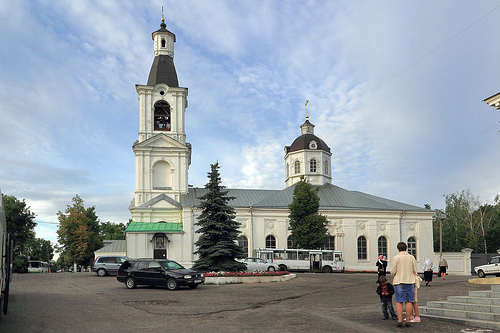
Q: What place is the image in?
A: It is at the church.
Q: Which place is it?
A: It is a church.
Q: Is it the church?
A: Yes, it is the church.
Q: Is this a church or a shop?
A: It is a church.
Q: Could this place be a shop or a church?
A: It is a church.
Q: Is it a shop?
A: No, it is a church.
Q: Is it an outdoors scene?
A: Yes, it is outdoors.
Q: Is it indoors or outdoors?
A: It is outdoors.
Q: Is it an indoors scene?
A: No, it is outdoors.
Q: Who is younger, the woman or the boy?
A: The boy is younger than the woman.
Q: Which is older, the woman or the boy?
A: The woman is older than the boy.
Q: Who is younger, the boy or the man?
A: The boy is younger than the man.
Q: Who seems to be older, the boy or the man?
A: The man is older than the boy.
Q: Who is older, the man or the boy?
A: The man is older than the boy.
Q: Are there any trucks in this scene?
A: No, there are no trucks.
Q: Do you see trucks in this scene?
A: No, there are no trucks.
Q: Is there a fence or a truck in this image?
A: No, there are no trucks or fences.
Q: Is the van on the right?
A: No, the van is on the left of the image.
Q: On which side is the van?
A: The van is on the left of the image.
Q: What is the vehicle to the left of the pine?
A: The vehicle is a van.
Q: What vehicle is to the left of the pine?
A: The vehicle is a van.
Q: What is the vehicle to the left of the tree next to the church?
A: The vehicle is a van.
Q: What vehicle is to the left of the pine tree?
A: The vehicle is a van.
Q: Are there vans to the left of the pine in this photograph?
A: Yes, there is a van to the left of the pine.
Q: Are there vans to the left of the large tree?
A: Yes, there is a van to the left of the pine.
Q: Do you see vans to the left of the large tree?
A: Yes, there is a van to the left of the pine.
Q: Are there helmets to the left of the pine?
A: No, there is a van to the left of the pine.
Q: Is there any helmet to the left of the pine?
A: No, there is a van to the left of the pine.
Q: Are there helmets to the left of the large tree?
A: No, there is a van to the left of the pine.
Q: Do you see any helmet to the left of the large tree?
A: No, there is a van to the left of the pine.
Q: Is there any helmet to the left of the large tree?
A: No, there is a van to the left of the pine.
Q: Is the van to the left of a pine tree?
A: Yes, the van is to the left of a pine tree.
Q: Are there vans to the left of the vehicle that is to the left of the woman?
A: Yes, there is a van to the left of the bus.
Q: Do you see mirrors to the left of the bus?
A: No, there is a van to the left of the bus.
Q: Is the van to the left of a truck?
A: No, the van is to the left of a bus.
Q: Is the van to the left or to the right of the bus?
A: The van is to the left of the bus.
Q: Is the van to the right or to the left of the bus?
A: The van is to the left of the bus.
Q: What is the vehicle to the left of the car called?
A: The vehicle is a van.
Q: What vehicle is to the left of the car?
A: The vehicle is a van.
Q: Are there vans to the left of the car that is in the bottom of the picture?
A: Yes, there is a van to the left of the car.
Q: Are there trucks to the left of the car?
A: No, there is a van to the left of the car.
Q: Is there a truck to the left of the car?
A: No, there is a van to the left of the car.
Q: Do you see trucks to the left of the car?
A: No, there is a van to the left of the car.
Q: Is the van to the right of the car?
A: No, the van is to the left of the car.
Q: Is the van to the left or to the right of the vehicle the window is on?
A: The van is to the left of the car.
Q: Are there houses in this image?
A: No, there are no houses.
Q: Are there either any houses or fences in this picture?
A: No, there are no houses or fences.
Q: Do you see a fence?
A: No, there are no fences.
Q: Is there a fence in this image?
A: No, there are no fences.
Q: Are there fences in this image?
A: No, there are no fences.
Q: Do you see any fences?
A: No, there are no fences.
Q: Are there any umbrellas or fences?
A: No, there are no fences or umbrellas.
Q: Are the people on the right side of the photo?
A: Yes, the people are on the right of the image.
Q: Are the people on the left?
A: No, the people are on the right of the image.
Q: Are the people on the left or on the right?
A: The people are on the right of the image.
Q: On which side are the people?
A: The people are on the right of the image.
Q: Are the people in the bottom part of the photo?
A: Yes, the people are in the bottom of the image.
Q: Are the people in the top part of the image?
A: No, the people are in the bottom of the image.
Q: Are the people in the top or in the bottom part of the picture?
A: The people are in the bottom of the image.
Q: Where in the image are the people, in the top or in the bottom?
A: The people are in the bottom of the image.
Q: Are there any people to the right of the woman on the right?
A: Yes, there are people to the right of the woman.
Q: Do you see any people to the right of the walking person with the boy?
A: Yes, there are people to the right of the woman.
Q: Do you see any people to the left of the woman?
A: No, the people are to the right of the woman.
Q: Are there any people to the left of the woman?
A: No, the people are to the right of the woman.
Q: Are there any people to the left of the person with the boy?
A: No, the people are to the right of the woman.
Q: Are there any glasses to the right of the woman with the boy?
A: No, there are people to the right of the woman.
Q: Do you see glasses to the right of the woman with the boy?
A: No, there are people to the right of the woman.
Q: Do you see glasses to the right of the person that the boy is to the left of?
A: No, there are people to the right of the woman.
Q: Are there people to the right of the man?
A: Yes, there are people to the right of the man.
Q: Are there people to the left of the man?
A: No, the people are to the right of the man.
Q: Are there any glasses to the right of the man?
A: No, there are people to the right of the man.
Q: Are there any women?
A: Yes, there is a woman.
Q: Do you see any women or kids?
A: Yes, there is a woman.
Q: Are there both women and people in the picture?
A: Yes, there are both a woman and a person.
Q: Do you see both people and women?
A: Yes, there are both a woman and a person.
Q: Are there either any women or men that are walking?
A: Yes, the woman is walking.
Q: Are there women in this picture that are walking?
A: Yes, there is a woman that is walking.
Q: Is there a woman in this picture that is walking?
A: Yes, there is a woman that is walking.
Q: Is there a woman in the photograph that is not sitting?
A: Yes, there is a woman that is walking.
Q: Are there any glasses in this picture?
A: No, there are no glasses.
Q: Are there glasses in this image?
A: No, there are no glasses.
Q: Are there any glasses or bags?
A: No, there are no glasses or bags.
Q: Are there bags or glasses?
A: No, there are no glasses or bags.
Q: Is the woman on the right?
A: Yes, the woman is on the right of the image.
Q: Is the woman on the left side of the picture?
A: No, the woman is on the right of the image.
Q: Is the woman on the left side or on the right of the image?
A: The woman is on the right of the image.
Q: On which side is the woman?
A: The woman is on the right of the image.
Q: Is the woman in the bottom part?
A: Yes, the woman is in the bottom of the image.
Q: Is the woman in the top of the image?
A: No, the woman is in the bottom of the image.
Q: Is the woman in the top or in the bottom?
A: The woman is in the bottom of the image.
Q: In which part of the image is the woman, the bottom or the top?
A: The woman is in the bottom of the image.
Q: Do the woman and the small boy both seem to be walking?
A: Yes, both the woman and the boy are walking.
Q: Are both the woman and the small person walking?
A: Yes, both the woman and the boy are walking.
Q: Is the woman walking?
A: Yes, the woman is walking.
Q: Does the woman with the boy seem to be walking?
A: Yes, the woman is walking.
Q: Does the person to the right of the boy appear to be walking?
A: Yes, the woman is walking.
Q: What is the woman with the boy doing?
A: The woman is walking.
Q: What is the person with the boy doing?
A: The woman is walking.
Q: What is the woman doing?
A: The woman is walking.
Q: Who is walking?
A: The woman is walking.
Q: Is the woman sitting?
A: No, the woman is walking.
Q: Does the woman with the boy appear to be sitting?
A: No, the woman is walking.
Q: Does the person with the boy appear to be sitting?
A: No, the woman is walking.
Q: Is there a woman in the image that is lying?
A: No, there is a woman but she is walking.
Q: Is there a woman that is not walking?
A: No, there is a woman but she is walking.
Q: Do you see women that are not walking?
A: No, there is a woman but she is walking.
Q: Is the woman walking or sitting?
A: The woman is walking.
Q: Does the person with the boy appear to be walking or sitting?
A: The woman is walking.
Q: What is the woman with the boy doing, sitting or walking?
A: The woman is walking.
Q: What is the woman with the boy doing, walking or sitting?
A: The woman is walking.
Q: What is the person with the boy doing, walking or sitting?
A: The woman is walking.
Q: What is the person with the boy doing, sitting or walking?
A: The woman is walking.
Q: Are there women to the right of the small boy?
A: Yes, there is a woman to the right of the boy.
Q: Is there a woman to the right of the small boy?
A: Yes, there is a woman to the right of the boy.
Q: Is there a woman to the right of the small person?
A: Yes, there is a woman to the right of the boy.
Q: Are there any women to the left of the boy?
A: No, the woman is to the right of the boy.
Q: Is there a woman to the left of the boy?
A: No, the woman is to the right of the boy.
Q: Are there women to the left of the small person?
A: No, the woman is to the right of the boy.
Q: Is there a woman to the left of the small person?
A: No, the woman is to the right of the boy.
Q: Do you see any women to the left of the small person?
A: No, the woman is to the right of the boy.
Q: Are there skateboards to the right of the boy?
A: No, there is a woman to the right of the boy.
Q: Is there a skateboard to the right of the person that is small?
A: No, there is a woman to the right of the boy.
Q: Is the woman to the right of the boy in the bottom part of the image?
A: Yes, the woman is to the right of the boy.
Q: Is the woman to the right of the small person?
A: Yes, the woman is to the right of the boy.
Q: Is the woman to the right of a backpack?
A: No, the woman is to the right of the boy.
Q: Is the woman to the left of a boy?
A: No, the woman is to the right of a boy.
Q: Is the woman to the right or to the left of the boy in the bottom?
A: The woman is to the right of the boy.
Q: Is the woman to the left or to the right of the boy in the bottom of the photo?
A: The woman is to the right of the boy.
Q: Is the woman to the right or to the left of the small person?
A: The woman is to the right of the boy.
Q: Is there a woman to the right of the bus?
A: Yes, there is a woman to the right of the bus.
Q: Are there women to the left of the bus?
A: No, the woman is to the right of the bus.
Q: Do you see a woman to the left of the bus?
A: No, the woman is to the right of the bus.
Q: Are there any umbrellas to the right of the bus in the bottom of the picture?
A: No, there is a woman to the right of the bus.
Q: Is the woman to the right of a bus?
A: Yes, the woman is to the right of a bus.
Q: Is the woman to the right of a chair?
A: No, the woman is to the right of a bus.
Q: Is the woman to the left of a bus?
A: No, the woman is to the right of a bus.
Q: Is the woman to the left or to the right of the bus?
A: The woman is to the right of the bus.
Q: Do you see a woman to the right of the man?
A: Yes, there is a woman to the right of the man.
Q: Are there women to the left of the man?
A: No, the woman is to the right of the man.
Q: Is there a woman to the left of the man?
A: No, the woman is to the right of the man.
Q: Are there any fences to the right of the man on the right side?
A: No, there is a woman to the right of the man.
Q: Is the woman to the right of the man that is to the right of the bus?
A: Yes, the woman is to the right of the man.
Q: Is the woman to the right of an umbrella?
A: No, the woman is to the right of the man.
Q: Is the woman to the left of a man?
A: No, the woman is to the right of a man.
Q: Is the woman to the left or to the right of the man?
A: The woman is to the right of the man.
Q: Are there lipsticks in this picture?
A: No, there are no lipsticks.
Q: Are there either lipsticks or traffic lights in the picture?
A: No, there are no lipsticks or traffic lights.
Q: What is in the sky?
A: The clouds are in the sky.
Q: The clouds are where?
A: The clouds are in the sky.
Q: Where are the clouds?
A: The clouds are in the sky.